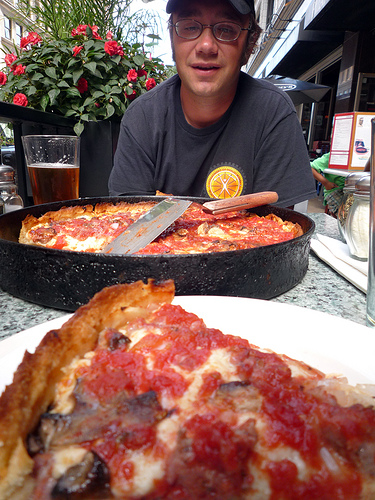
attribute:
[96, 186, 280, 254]
slicer — pizza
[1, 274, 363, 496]
slice — pizza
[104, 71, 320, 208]
t-shirt — black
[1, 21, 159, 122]
plant — flowered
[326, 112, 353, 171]
menu — restaurant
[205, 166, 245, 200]
logo — orange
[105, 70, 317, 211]
shirt — Black, men's, tee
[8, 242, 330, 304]
skillet — cast iron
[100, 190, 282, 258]
utensil — serving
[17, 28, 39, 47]
flowers — red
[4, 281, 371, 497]
casserole — slice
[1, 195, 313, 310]
pizza — large, deep dish, pepperoni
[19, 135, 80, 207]
glass — beer, nice, cold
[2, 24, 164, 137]
carnations — beautiful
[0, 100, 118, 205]
pot — nice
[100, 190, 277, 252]
spatula — large, metal, wood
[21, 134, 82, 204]
beer — amber colored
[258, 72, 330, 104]
umbrella — blue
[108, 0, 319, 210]
man — hungry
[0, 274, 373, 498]
pizza — cheesy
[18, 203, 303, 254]
pizza — entire